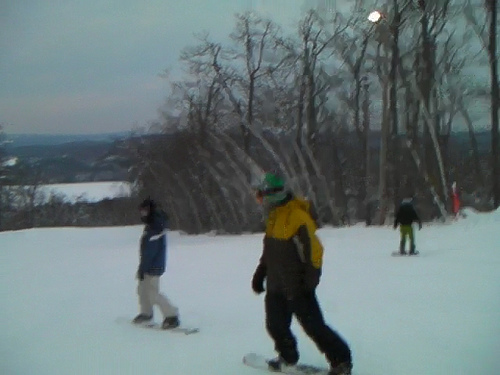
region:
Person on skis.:
[233, 155, 374, 369]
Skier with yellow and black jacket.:
[223, 158, 348, 368]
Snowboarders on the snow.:
[92, 161, 347, 369]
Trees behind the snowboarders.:
[108, 22, 473, 276]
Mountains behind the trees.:
[15, 94, 170, 228]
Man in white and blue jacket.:
[98, 195, 194, 295]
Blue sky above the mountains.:
[18, 55, 165, 176]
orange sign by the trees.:
[422, 145, 492, 240]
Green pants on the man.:
[387, 219, 434, 268]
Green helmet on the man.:
[239, 170, 295, 220]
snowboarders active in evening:
[85, 118, 461, 359]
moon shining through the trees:
[340, 5, 401, 45]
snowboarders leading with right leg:
[105, 170, 377, 371]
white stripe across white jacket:
[126, 190, 186, 330]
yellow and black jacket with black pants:
[235, 156, 360, 353]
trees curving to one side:
[130, 106, 330, 246]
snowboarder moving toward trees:
[376, 155, 436, 285]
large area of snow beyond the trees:
[0, 172, 126, 214]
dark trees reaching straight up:
[212, 12, 418, 133]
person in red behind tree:
[427, 145, 478, 226]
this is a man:
[220, 170, 340, 364]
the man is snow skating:
[226, 162, 327, 369]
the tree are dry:
[163, 0, 432, 175]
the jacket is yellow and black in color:
[265, 214, 305, 290]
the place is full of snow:
[3, 232, 115, 372]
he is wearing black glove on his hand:
[248, 272, 263, 288]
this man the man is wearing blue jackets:
[141, 225, 165, 265]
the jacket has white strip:
[146, 227, 163, 247]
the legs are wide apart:
[272, 310, 327, 355]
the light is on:
[363, 7, 385, 19]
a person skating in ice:
[241, 157, 360, 369]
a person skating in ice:
[116, 191, 186, 334]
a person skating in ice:
[389, 191, 424, 264]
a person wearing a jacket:
[238, 177, 353, 373]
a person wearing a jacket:
[120, 191, 183, 323]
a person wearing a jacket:
[385, 185, 424, 262]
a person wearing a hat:
[117, 187, 191, 343]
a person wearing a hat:
[245, 170, 360, 370]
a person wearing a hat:
[379, 182, 431, 267]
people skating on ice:
[93, 157, 424, 373]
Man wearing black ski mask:
[136, 180, 175, 237]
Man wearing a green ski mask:
[241, 167, 311, 209]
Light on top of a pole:
[343, 9, 425, 38]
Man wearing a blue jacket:
[116, 213, 206, 275]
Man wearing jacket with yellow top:
[251, 189, 350, 302]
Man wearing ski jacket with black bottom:
[238, 205, 355, 300]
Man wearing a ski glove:
[238, 260, 288, 295]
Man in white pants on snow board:
[106, 307, 248, 341]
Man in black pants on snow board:
[227, 325, 409, 372]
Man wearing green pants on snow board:
[386, 218, 443, 268]